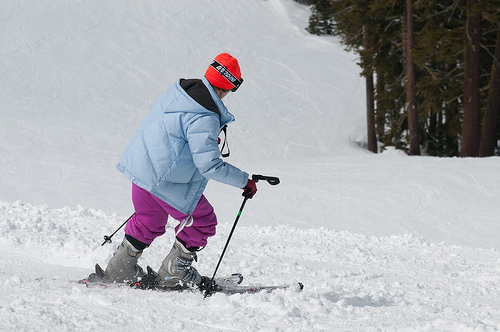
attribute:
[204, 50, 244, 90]
hat — red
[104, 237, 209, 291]
boots — ski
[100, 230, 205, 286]
boots — grey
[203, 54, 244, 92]
hat — orange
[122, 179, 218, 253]
pants — purple, ski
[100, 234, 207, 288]
boots — ski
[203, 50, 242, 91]
beanie — orange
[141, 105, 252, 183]
jacket — blue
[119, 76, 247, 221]
jacket — blue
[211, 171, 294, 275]
pole — ski, black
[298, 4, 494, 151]
trees — several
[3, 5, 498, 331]
snow — white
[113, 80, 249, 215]
coat — black, blue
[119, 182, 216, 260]
pants — purple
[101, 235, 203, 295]
boots — gray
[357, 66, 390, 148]
trunk — brown